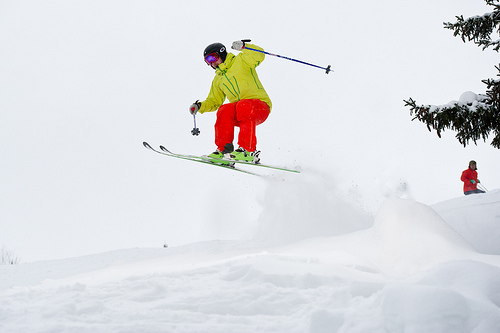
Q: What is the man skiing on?
A: Snow.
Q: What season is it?
A: Winter.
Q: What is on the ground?
A: Snow.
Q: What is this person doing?
A: Skiing.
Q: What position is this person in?
A: Jumping position.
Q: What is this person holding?
A: Ski poles.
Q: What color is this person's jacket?
A: Bright yellow.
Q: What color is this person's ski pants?
A: Bright orange.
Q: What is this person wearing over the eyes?
A: Goggles.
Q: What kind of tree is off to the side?
A: Pine tree.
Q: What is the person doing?
A: Skiing.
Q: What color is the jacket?
A: Yellow.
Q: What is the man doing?
A: Jumping in the air.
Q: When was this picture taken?
A: Winter.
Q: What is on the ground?
A: Snow.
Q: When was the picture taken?
A: Daytime.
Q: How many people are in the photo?
A: Two.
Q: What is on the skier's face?
A: Goggles.